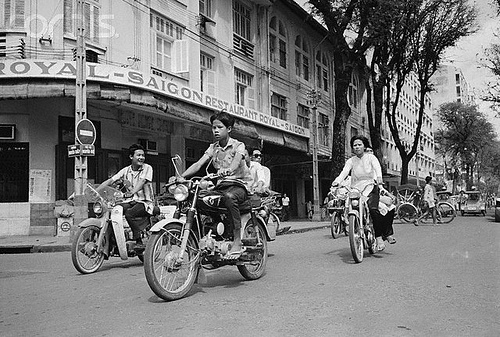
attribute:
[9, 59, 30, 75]
letter — black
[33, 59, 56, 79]
letter — black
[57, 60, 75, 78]
letter — black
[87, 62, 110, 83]
letter — black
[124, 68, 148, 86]
letter — black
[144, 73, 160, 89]
letter — black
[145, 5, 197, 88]
window — large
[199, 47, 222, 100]
window — large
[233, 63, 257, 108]
window — large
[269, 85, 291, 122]
window — large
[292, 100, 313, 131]
window — large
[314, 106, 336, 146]
window — large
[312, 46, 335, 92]
window — large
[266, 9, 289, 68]
window — large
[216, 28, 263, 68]
window — large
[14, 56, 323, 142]
sign — long, banner style, for a restaurant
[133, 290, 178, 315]
shadow — bike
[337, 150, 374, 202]
shirt — white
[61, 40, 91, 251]
post — tall, street light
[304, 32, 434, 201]
tree — tall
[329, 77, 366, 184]
trunk — thick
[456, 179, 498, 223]
car — parked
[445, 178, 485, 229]
trunk — open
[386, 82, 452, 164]
building — white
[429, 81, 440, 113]
windows — long, rectangular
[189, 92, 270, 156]
hair — short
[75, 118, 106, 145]
sign — circle shaped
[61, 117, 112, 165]
sign — circle shaped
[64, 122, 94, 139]
stripe — white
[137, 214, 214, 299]
wheel — dark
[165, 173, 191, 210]
headlight — round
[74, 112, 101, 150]
sign — circular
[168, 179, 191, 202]
headlight — glass 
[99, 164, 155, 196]
shirt — striped 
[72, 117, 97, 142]
sign — round 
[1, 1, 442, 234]
building — curved sign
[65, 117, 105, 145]
sign — round, block line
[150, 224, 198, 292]
tire — bike   , spokes 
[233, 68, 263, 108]
window —  open shutter